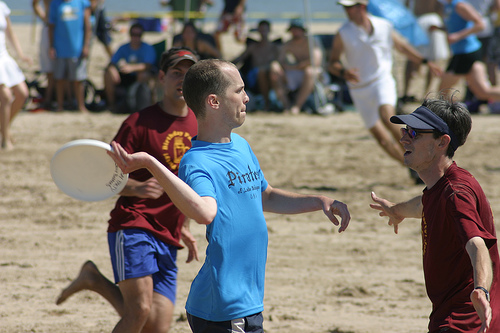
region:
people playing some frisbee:
[82, 51, 467, 285]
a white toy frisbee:
[54, 126, 155, 201]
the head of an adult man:
[395, 91, 462, 176]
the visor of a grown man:
[400, 96, 450, 137]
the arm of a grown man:
[362, 179, 440, 233]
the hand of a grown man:
[315, 191, 352, 236]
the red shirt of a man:
[418, 186, 490, 321]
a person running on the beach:
[330, 6, 400, 138]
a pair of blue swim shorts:
[97, 213, 189, 308]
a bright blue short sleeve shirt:
[185, 143, 269, 314]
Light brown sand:
[8, 105, 491, 330]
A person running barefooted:
[41, 42, 211, 327]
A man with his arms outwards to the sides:
[362, 76, 497, 317]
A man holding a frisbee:
[50, 50, 360, 325]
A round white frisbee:
[50, 131, 137, 201]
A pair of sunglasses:
[390, 120, 440, 140]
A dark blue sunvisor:
[388, 103, 460, 148]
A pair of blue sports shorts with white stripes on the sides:
[107, 230, 178, 307]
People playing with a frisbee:
[22, 25, 479, 330]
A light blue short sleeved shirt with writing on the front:
[179, 131, 282, 321]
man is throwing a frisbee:
[51, 57, 351, 329]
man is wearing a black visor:
[368, 97, 496, 330]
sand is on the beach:
[2, 108, 497, 329]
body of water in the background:
[1, 0, 492, 25]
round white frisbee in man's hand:
[49, 137, 129, 204]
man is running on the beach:
[55, 46, 199, 328]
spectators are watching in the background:
[28, 0, 498, 114]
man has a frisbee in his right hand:
[50, 56, 351, 328]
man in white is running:
[327, 2, 442, 184]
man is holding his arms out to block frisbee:
[366, 95, 496, 330]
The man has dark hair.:
[419, 93, 478, 148]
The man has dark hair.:
[171, 55, 243, 110]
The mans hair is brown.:
[413, 85, 483, 157]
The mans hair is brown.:
[172, 53, 242, 108]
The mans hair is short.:
[412, 85, 472, 160]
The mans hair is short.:
[184, 57, 239, 114]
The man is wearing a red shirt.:
[403, 163, 495, 332]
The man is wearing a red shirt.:
[121, 98, 186, 240]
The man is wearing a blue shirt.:
[155, 133, 280, 323]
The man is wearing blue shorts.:
[101, 220, 177, 302]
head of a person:
[165, 58, 260, 145]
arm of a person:
[135, 146, 236, 231]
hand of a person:
[97, 119, 142, 186]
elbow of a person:
[193, 216, 223, 233]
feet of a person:
[50, 246, 114, 328]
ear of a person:
[202, 93, 229, 113]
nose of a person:
[239, 91, 251, 105]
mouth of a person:
[227, 105, 255, 120]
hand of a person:
[375, 176, 412, 236]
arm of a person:
[387, 193, 431, 230]